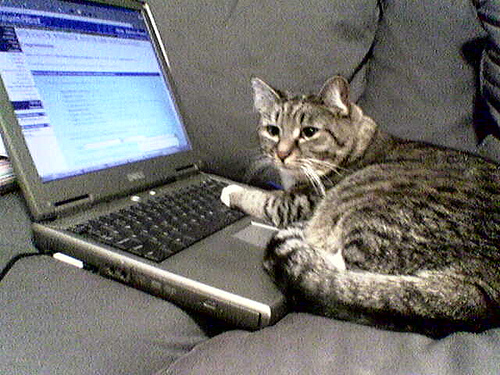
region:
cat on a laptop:
[189, 87, 497, 341]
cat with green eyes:
[256, 119, 331, 143]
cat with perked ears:
[232, 65, 361, 126]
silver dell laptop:
[114, 157, 172, 216]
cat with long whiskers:
[230, 140, 347, 195]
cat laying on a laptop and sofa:
[235, 70, 495, 312]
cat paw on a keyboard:
[217, 161, 264, 233]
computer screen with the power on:
[5, 4, 198, 178]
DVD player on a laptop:
[130, 268, 265, 332]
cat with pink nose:
[271, 143, 293, 166]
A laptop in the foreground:
[1, 0, 316, 340]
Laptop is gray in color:
[2, 1, 322, 333]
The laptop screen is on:
[1, 2, 199, 192]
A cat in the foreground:
[209, 65, 498, 335]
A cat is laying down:
[216, 65, 498, 341]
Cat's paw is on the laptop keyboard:
[211, 172, 308, 239]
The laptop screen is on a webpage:
[2, 3, 207, 192]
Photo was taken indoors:
[2, 3, 492, 373]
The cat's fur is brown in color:
[208, 65, 495, 343]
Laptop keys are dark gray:
[61, 173, 254, 288]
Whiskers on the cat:
[298, 154, 346, 196]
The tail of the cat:
[271, 223, 498, 323]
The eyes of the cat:
[263, 123, 318, 139]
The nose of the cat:
[276, 150, 288, 158]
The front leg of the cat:
[220, 183, 291, 223]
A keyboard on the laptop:
[65, 178, 251, 263]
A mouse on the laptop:
[234, 220, 278, 246]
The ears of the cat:
[249, 75, 351, 112]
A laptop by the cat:
[1, 0, 295, 327]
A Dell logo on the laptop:
[126, 169, 147, 181]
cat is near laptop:
[201, 103, 496, 325]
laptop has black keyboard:
[78, 177, 273, 272]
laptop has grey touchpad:
[242, 217, 277, 254]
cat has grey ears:
[254, 77, 352, 128]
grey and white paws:
[204, 131, 346, 251]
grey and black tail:
[230, 228, 491, 325]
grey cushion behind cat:
[228, 1, 455, 123]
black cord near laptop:
[1, 234, 63, 295]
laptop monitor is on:
[4, 10, 201, 178]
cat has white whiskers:
[250, 138, 342, 208]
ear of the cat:
[317, 68, 349, 112]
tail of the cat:
[257, 229, 483, 324]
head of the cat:
[237, 78, 362, 177]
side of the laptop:
[48, 249, 260, 327]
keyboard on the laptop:
[110, 204, 212, 246]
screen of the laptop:
[37, 67, 183, 157]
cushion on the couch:
[89, 336, 339, 373]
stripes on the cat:
[384, 220, 452, 274]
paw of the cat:
[208, 183, 279, 220]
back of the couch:
[342, 40, 450, 85]